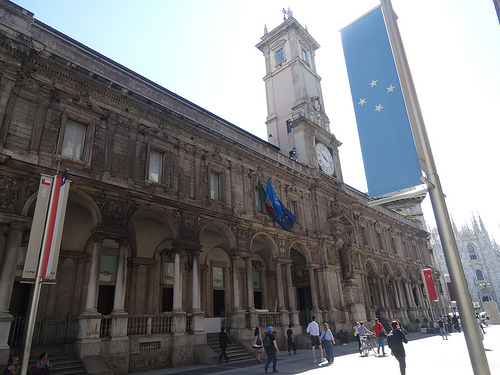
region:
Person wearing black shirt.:
[381, 326, 394, 341]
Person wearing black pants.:
[384, 345, 412, 372]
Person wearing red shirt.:
[373, 317, 382, 334]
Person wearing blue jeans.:
[369, 339, 391, 358]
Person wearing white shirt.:
[309, 319, 332, 343]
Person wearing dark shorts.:
[306, 338, 329, 358]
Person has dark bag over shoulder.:
[369, 325, 397, 347]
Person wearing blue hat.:
[262, 325, 278, 336]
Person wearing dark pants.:
[258, 348, 280, 359]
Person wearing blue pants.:
[318, 341, 339, 361]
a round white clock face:
[308, 138, 339, 176]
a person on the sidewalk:
[258, 323, 284, 373]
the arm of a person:
[268, 334, 278, 350]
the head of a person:
[263, 322, 275, 334]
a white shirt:
[303, 320, 323, 335]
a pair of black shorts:
[306, 333, 321, 348]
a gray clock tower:
[255, 10, 345, 175]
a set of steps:
[200, 323, 254, 365]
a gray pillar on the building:
[106, 241, 133, 317]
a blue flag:
[262, 175, 294, 226]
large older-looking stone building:
[2, 1, 449, 373]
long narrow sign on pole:
[18, 158, 78, 374]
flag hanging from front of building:
[235, 162, 312, 248]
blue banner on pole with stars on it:
[340, 0, 491, 374]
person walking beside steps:
[195, 293, 255, 370]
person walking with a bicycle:
[348, 305, 384, 365]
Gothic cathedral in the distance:
[405, 190, 497, 342]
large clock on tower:
[289, 117, 344, 182]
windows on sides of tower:
[257, 30, 322, 76]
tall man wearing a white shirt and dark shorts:
[295, 306, 328, 372]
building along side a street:
[5, 3, 493, 373]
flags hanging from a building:
[244, 166, 307, 238]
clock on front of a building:
[308, 136, 343, 177]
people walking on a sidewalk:
[218, 311, 425, 374]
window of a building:
[143, 136, 175, 192]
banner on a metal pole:
[327, 1, 480, 373]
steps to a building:
[56, 348, 82, 373]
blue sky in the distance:
[41, 3, 177, 33]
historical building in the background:
[425, 211, 498, 329]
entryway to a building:
[205, 286, 234, 323]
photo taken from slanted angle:
[0, 1, 495, 372]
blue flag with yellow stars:
[330, 0, 460, 206]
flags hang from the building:
[245, 171, 305, 252]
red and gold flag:
[416, 257, 441, 312]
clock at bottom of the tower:
[270, 10, 345, 185]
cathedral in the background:
[421, 211, 493, 301]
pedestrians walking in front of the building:
[185, 291, 480, 371]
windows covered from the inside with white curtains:
[16, 110, 246, 205]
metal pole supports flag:
[333, 1, 494, 372]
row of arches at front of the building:
[2, 180, 447, 371]